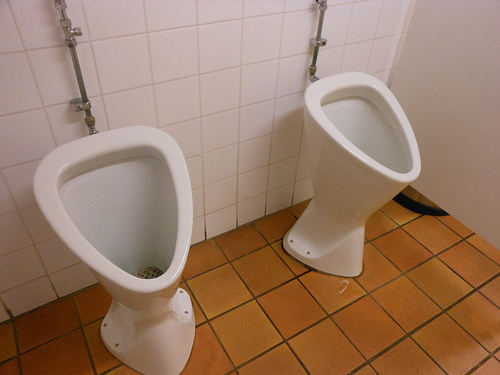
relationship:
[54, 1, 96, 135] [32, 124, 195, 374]
pipe attached to urinal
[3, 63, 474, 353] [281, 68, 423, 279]
bathroom has toilet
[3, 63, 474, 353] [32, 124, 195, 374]
bathroom has urinal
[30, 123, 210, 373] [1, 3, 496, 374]
urinal in bathroom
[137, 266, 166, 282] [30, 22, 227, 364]
drain at urinal